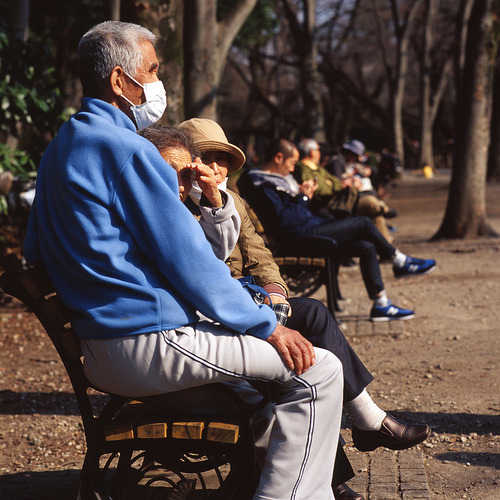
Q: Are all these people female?
A: No, they are both male and female.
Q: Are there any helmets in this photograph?
A: No, there are no helmets.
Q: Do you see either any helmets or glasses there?
A: No, there are no helmets or glasses.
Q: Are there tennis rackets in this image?
A: No, there are no tennis rackets.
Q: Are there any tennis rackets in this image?
A: No, there are no tennis rackets.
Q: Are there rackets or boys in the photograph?
A: No, there are no rackets or boys.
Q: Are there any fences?
A: No, there are no fences.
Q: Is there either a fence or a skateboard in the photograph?
A: No, there are no fences or skateboards.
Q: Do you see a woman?
A: Yes, there is a woman.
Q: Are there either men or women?
A: Yes, there is a woman.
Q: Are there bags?
A: No, there are no bags.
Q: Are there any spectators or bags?
A: No, there are no bags or spectators.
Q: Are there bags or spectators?
A: No, there are no bags or spectators.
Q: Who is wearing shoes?
A: The woman is wearing shoes.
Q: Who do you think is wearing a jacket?
A: The woman is wearing a jacket.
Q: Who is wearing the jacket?
A: The woman is wearing a jacket.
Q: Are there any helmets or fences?
A: No, there are no fences or helmets.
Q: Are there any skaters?
A: No, there are no skaters.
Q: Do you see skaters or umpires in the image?
A: No, there are no skaters or umpires.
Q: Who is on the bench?
A: The man is on the bench.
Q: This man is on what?
A: The man is on the bench.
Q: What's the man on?
A: The man is on the bench.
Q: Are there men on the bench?
A: Yes, there is a man on the bench.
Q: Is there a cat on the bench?
A: No, there is a man on the bench.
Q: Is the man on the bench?
A: Yes, the man is on the bench.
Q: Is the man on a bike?
A: No, the man is on the bench.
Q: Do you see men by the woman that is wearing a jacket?
A: Yes, there is a man by the woman.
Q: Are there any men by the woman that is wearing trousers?
A: Yes, there is a man by the woman.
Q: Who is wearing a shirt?
A: The man is wearing a shirt.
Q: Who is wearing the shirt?
A: The man is wearing a shirt.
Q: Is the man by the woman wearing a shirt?
A: Yes, the man is wearing a shirt.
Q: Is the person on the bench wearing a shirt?
A: Yes, the man is wearing a shirt.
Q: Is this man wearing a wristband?
A: No, the man is wearing a shirt.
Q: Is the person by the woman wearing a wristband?
A: No, the man is wearing a shirt.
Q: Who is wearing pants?
A: The man is wearing pants.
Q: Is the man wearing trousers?
A: Yes, the man is wearing trousers.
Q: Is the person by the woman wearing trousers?
A: Yes, the man is wearing trousers.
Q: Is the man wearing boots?
A: No, the man is wearing trousers.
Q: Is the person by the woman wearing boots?
A: No, the man is wearing trousers.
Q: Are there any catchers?
A: No, there are no catchers.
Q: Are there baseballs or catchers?
A: No, there are no catchers or baseballs.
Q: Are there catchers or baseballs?
A: No, there are no catchers or baseballs.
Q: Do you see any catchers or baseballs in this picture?
A: No, there are no catchers or baseballs.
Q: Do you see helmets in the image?
A: No, there are no helmets.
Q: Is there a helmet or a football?
A: No, there are no helmets or footballs.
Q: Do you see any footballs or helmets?
A: No, there are no helmets or footballs.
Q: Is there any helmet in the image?
A: No, there are no helmets.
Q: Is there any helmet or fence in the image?
A: No, there are no helmets or fences.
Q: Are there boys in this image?
A: No, there are no boys.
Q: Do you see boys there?
A: No, there are no boys.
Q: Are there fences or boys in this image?
A: No, there are no boys or fences.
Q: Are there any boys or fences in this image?
A: No, there are no boys or fences.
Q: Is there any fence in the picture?
A: No, there are no fences.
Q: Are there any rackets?
A: No, there are no rackets.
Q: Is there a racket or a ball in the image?
A: No, there are no rackets or balls.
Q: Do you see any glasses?
A: No, there are no glasses.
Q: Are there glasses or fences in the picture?
A: No, there are no glasses or fences.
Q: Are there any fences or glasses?
A: No, there are no glasses or fences.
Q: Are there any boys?
A: No, there are no boys.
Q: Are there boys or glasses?
A: No, there are no boys or glasses.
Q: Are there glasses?
A: No, there are no glasses.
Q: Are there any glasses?
A: No, there are no glasses.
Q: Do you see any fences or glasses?
A: No, there are no glasses or fences.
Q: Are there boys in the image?
A: No, there are no boys.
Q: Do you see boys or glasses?
A: No, there are no boys or glasses.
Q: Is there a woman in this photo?
A: Yes, there is a woman.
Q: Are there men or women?
A: Yes, there is a woman.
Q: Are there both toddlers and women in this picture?
A: No, there is a woman but no toddlers.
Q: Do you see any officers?
A: No, there are no officers.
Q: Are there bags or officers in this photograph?
A: No, there are no officers or bags.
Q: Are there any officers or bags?
A: No, there are no officers or bags.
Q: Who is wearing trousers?
A: The woman is wearing trousers.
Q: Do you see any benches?
A: Yes, there is a bench.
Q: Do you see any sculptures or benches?
A: Yes, there is a bench.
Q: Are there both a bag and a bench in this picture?
A: No, there is a bench but no bags.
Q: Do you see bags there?
A: No, there are no bags.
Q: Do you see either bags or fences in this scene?
A: No, there are no bags or fences.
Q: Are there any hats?
A: Yes, there is a hat.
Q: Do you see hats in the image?
A: Yes, there is a hat.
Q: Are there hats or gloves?
A: Yes, there is a hat.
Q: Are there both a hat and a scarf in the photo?
A: No, there is a hat but no scarves.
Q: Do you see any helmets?
A: No, there are no helmets.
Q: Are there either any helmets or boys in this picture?
A: No, there are no helmets or boys.